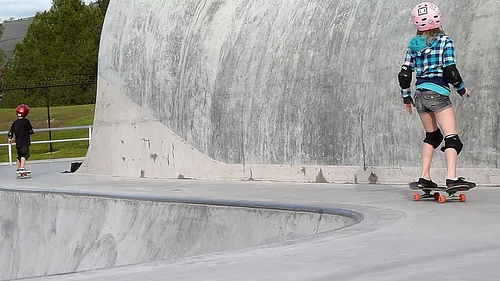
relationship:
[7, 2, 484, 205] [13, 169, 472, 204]
kids are riding on skateboards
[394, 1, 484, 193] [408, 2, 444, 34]
kids wearing helmet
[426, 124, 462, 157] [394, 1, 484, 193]
kneepad located on kids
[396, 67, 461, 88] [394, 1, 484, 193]
elbow pads are worn by kids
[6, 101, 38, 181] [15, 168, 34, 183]
boy riding on skateboard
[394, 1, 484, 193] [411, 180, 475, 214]
kids riding on skateboard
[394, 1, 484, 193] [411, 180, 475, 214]
kids riding skateboard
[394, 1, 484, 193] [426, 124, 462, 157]
kids wearing kneepad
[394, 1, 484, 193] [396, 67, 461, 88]
kids wearing elbow pads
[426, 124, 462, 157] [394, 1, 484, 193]
kneepad worn by kids